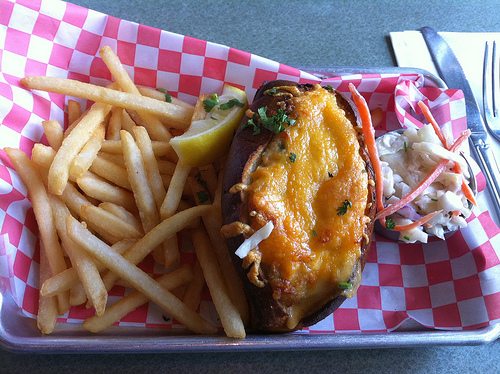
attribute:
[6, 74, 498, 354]
tray — gray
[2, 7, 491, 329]
paper — red, white, checkered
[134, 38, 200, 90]
paper — red, white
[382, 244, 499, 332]
tray cover — red, white, checkered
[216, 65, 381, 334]
potato — loaded baked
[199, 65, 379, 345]
potato — baked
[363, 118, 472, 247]
cup — small